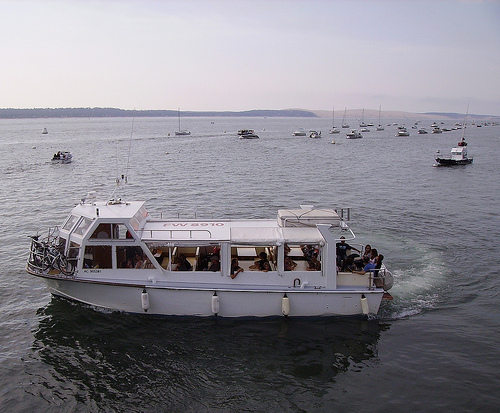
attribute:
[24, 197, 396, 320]
boat — large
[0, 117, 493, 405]
water — gray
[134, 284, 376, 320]
bouys — white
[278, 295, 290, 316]
buoy — white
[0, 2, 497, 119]
sky — clear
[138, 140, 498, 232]
water — bubbly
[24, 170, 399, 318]
boat — white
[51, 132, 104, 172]
bouy — white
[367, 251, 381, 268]
person — white